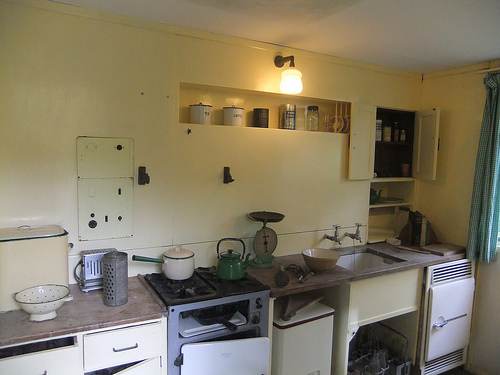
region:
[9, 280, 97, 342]
white colander on table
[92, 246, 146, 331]
grater on table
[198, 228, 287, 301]
green kettle on the stove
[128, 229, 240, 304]
white and green pot on stove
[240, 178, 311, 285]
green scale on table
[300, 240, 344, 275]
bowl on the table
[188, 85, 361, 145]
containers on shelf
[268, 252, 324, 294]
utensils on table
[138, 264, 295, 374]
broken stove in cabinet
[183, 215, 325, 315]
a teapot on teh stove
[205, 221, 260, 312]
a green teapot on the stove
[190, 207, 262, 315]
a teapot on the kitchen stove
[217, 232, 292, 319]
a teapot on the gass stove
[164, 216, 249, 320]
green teapot on gas stove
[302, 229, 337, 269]
a bowl on the counter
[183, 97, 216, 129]
White container on shelf.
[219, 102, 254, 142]
White container on shelf.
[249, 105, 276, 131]
Black container on shelf.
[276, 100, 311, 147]
Silver container on shelf.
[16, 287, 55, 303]
White strainer on counter.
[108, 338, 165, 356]
Gray handle on drawer.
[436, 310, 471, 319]
Silver handle on door.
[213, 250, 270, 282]
Green tea kettle on burner.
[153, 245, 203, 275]
White pot on burner.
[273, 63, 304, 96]
A light is turned on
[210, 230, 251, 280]
A tea kettle is green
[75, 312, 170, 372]
A white wooden drawer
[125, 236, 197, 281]
A white pot with a green handle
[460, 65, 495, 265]
The curtains are blue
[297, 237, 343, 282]
A bowl on the countertop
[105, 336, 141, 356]
The handle of a drawer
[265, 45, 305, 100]
A light fixture on the wall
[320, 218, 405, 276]
Two faucets over a sink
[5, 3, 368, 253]
bare white kitchen wall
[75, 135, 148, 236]
left behind sockets from missing appliance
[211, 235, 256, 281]
green tea kettle on the stove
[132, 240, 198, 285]
white and green pot on the stove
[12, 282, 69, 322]
white colander on gray countertop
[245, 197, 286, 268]
metal green scale on gray counter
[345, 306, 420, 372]
small open dishwasher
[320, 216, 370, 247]
old style sink faucets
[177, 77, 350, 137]
built-in shelf with containers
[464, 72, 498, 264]
blue and white checkered curtain